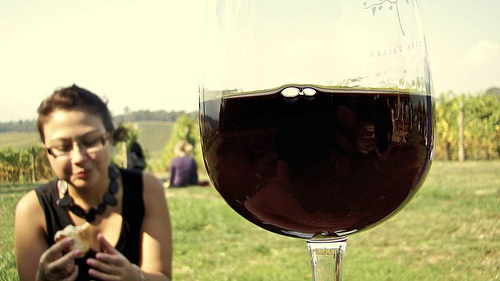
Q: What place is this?
A: It is a field.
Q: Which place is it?
A: It is a field.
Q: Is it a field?
A: Yes, it is a field.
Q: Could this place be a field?
A: Yes, it is a field.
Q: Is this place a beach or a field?
A: It is a field.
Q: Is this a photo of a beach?
A: No, the picture is showing a field.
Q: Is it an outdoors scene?
A: Yes, it is outdoors.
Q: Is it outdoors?
A: Yes, it is outdoors.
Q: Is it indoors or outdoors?
A: It is outdoors.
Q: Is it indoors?
A: No, it is outdoors.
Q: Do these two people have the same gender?
A: Yes, all the people are female.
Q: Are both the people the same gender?
A: Yes, all the people are female.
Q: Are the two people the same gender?
A: Yes, all the people are female.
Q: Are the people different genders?
A: No, all the people are female.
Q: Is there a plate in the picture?
A: No, there are no plates.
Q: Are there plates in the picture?
A: No, there are no plates.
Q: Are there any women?
A: Yes, there is a woman.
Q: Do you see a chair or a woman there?
A: Yes, there is a woman.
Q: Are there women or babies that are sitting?
A: Yes, the woman is sitting.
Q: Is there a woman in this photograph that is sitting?
A: Yes, there is a woman that is sitting.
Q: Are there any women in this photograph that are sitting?
A: Yes, there is a woman that is sitting.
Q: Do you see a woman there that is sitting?
A: Yes, there is a woman that is sitting.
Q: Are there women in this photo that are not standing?
A: Yes, there is a woman that is sitting.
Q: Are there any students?
A: No, there are no students.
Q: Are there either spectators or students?
A: No, there are no students or spectators.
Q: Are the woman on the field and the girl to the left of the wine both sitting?
A: Yes, both the woman and the girl are sitting.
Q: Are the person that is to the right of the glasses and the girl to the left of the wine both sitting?
A: Yes, both the woman and the girl are sitting.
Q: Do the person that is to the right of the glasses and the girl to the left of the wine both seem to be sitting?
A: Yes, both the woman and the girl are sitting.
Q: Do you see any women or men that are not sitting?
A: No, there is a woman but she is sitting.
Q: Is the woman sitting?
A: Yes, the woman is sitting.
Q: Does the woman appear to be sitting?
A: Yes, the woman is sitting.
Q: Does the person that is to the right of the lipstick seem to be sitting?
A: Yes, the woman is sitting.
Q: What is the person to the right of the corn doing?
A: The woman is sitting.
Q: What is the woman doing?
A: The woman is sitting.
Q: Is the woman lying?
A: No, the woman is sitting.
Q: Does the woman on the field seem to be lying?
A: No, the woman is sitting.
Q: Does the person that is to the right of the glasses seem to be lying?
A: No, the woman is sitting.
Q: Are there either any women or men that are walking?
A: No, there is a woman but she is sitting.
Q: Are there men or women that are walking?
A: No, there is a woman but she is sitting.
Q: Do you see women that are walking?
A: No, there is a woman but she is sitting.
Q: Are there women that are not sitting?
A: No, there is a woman but she is sitting.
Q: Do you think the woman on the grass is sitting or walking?
A: The woman is sitting.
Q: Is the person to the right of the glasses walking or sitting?
A: The woman is sitting.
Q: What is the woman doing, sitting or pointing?
A: The woman is sitting.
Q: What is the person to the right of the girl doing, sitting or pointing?
A: The woman is sitting.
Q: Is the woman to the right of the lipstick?
A: Yes, the woman is to the right of the lipstick.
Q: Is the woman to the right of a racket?
A: No, the woman is to the right of the lipstick.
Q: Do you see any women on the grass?
A: Yes, there is a woman on the grass.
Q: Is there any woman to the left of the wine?
A: Yes, there is a woman to the left of the wine.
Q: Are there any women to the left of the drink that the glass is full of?
A: Yes, there is a woman to the left of the wine.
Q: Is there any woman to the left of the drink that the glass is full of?
A: Yes, there is a woman to the left of the wine.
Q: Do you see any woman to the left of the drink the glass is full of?
A: Yes, there is a woman to the left of the wine.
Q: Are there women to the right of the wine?
A: No, the woman is to the left of the wine.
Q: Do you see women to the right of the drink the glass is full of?
A: No, the woman is to the left of the wine.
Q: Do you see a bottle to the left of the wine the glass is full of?
A: No, there is a woman to the left of the wine.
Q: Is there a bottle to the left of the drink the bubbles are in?
A: No, there is a woman to the left of the wine.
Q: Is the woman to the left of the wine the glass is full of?
A: Yes, the woman is to the left of the wine.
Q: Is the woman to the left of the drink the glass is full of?
A: Yes, the woman is to the left of the wine.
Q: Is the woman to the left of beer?
A: No, the woman is to the left of the wine.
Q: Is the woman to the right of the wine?
A: No, the woman is to the left of the wine.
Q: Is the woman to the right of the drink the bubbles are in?
A: No, the woman is to the left of the wine.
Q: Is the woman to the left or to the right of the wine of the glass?
A: The woman is to the left of the wine.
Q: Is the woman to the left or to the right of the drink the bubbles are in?
A: The woman is to the left of the wine.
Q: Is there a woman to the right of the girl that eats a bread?
A: Yes, there is a woman to the right of the girl.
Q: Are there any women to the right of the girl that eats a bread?
A: Yes, there is a woman to the right of the girl.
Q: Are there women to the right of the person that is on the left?
A: Yes, there is a woman to the right of the girl.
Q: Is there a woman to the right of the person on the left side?
A: Yes, there is a woman to the right of the girl.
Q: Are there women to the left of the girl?
A: No, the woman is to the right of the girl.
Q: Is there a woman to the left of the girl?
A: No, the woman is to the right of the girl.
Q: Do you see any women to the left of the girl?
A: No, the woman is to the right of the girl.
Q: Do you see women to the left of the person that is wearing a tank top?
A: No, the woman is to the right of the girl.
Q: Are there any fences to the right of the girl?
A: No, there is a woman to the right of the girl.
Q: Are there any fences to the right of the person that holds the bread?
A: No, there is a woman to the right of the girl.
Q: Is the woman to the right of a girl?
A: Yes, the woman is to the right of a girl.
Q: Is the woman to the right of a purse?
A: No, the woman is to the right of a girl.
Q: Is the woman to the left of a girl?
A: No, the woman is to the right of a girl.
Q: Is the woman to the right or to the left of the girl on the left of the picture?
A: The woman is to the right of the girl.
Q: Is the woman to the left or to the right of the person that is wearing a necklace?
A: The woman is to the right of the girl.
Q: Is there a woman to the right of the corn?
A: Yes, there is a woman to the right of the corn.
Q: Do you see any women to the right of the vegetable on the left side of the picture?
A: Yes, there is a woman to the right of the corn.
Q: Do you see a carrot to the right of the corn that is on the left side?
A: No, there is a woman to the right of the corn.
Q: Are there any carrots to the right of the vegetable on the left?
A: No, there is a woman to the right of the corn.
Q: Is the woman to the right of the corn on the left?
A: Yes, the woman is to the right of the corn.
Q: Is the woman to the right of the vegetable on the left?
A: Yes, the woman is to the right of the corn.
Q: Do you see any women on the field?
A: Yes, there is a woman on the field.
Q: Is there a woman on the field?
A: Yes, there is a woman on the field.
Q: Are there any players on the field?
A: No, there is a woman on the field.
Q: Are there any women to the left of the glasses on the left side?
A: No, the woman is to the right of the glasses.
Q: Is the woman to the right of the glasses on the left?
A: Yes, the woman is to the right of the glasses.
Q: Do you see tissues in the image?
A: No, there are no tissues.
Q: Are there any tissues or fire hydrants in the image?
A: No, there are no tissues or fire hydrants.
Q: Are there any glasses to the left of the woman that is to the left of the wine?
A: Yes, there are glasses to the left of the woman.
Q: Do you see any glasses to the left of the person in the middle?
A: Yes, there are glasses to the left of the woman.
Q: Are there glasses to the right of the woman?
A: No, the glasses are to the left of the woman.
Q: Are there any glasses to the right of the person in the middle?
A: No, the glasses are to the left of the woman.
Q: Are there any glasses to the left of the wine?
A: Yes, there are glasses to the left of the wine.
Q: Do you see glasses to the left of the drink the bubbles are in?
A: Yes, there are glasses to the left of the wine.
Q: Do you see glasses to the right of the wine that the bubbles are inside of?
A: No, the glasses are to the left of the wine.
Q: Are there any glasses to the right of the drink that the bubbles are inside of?
A: No, the glasses are to the left of the wine.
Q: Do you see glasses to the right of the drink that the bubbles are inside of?
A: No, the glasses are to the left of the wine.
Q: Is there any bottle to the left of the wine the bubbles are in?
A: No, there are glasses to the left of the wine.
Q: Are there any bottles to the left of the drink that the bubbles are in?
A: No, there are glasses to the left of the wine.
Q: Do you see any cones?
A: No, there are no cones.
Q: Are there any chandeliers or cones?
A: No, there are no cones or chandeliers.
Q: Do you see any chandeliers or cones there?
A: No, there are no cones or chandeliers.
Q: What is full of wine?
A: The glass is full of wine.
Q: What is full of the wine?
A: The glass is full of wine.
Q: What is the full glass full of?
A: The glass is full of wine.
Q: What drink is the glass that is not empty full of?
A: The glass is full of wine.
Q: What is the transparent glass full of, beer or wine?
A: The glass is full of wine.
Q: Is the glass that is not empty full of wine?
A: Yes, the glass is full of wine.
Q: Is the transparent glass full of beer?
A: No, the glass is full of wine.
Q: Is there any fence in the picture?
A: No, there are no fences.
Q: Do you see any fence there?
A: No, there are no fences.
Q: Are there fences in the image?
A: No, there are no fences.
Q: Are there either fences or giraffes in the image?
A: No, there are no fences or giraffes.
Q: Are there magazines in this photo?
A: No, there are no magazines.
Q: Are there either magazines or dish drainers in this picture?
A: No, there are no magazines or dish drainers.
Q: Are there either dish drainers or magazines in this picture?
A: No, there are no magazines or dish drainers.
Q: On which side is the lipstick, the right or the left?
A: The lipstick is on the left of the image.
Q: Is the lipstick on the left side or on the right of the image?
A: The lipstick is on the left of the image.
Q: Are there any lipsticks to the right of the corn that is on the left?
A: Yes, there is a lipstick to the right of the corn.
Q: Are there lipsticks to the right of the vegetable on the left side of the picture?
A: Yes, there is a lipstick to the right of the corn.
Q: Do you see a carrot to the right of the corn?
A: No, there is a lipstick to the right of the corn.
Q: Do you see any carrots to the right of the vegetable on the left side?
A: No, there is a lipstick to the right of the corn.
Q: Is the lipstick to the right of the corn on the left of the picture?
A: Yes, the lipstick is to the right of the corn.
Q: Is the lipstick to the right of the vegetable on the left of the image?
A: Yes, the lipstick is to the right of the corn.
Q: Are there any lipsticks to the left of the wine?
A: Yes, there is a lipstick to the left of the wine.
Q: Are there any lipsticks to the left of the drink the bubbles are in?
A: Yes, there is a lipstick to the left of the wine.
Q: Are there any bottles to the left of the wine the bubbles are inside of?
A: No, there is a lipstick to the left of the wine.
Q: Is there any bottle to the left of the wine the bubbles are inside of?
A: No, there is a lipstick to the left of the wine.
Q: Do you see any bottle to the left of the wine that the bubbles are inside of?
A: No, there is a lipstick to the left of the wine.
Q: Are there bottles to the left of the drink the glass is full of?
A: No, there is a lipstick to the left of the wine.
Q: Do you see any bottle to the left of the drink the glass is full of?
A: No, there is a lipstick to the left of the wine.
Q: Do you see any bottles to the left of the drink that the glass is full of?
A: No, there is a lipstick to the left of the wine.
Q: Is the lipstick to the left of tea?
A: No, the lipstick is to the left of the wine.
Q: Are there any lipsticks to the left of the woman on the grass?
A: Yes, there is a lipstick to the left of the woman.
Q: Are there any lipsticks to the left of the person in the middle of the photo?
A: Yes, there is a lipstick to the left of the woman.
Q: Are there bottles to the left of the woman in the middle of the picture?
A: No, there is a lipstick to the left of the woman.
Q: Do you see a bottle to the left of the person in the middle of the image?
A: No, there is a lipstick to the left of the woman.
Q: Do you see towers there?
A: No, there are no towers.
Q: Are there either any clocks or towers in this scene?
A: No, there are no towers or clocks.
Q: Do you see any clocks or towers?
A: No, there are no towers or clocks.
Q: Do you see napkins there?
A: No, there are no napkins.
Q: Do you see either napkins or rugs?
A: No, there are no napkins or rugs.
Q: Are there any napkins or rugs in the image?
A: No, there are no napkins or rugs.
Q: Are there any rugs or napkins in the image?
A: No, there are no napkins or rugs.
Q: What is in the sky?
A: The clouds are in the sky.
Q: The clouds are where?
A: The clouds are in the sky.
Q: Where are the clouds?
A: The clouds are in the sky.